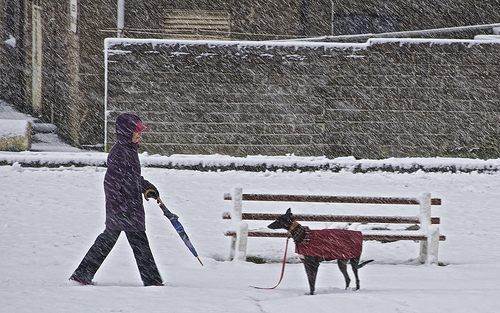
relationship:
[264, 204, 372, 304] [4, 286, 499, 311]
dog standing in snow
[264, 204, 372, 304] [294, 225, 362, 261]
dog wearing sweater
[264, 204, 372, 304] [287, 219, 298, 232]
dog wearing a collar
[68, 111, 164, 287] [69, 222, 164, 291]
boy wearing pants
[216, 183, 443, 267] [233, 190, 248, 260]
bench has snow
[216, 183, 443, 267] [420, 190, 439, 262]
bench has snow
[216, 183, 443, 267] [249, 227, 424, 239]
bench has snow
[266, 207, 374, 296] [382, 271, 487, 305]
dog in snow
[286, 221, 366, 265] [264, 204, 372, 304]
outfit on dog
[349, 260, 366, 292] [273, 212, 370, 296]
leg on dog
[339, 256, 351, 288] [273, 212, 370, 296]
leg on dog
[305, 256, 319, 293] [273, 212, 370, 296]
leg on dog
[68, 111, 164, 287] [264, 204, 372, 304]
boy next to dog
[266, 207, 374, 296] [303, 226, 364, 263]
dog with a blanket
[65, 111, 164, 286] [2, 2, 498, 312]
boy in snow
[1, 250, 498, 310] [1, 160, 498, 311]
path covered in snow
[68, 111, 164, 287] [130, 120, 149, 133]
boy wearing hat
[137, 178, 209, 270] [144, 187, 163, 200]
item in person's hand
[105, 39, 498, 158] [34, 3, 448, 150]
wall in background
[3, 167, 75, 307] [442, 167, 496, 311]
snow in snow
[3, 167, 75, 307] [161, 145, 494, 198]
snow in snow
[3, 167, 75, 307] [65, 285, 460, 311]
snow in snow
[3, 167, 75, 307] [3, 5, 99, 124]
snow in snow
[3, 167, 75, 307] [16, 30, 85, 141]
snow in air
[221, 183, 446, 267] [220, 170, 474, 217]
bench in snow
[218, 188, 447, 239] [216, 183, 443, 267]
back of bench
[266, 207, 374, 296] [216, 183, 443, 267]
dog in front of bench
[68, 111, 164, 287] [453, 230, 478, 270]
boy walking in snow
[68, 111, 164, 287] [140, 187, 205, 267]
boy carrying umbrella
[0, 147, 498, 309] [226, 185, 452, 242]
snow on bench